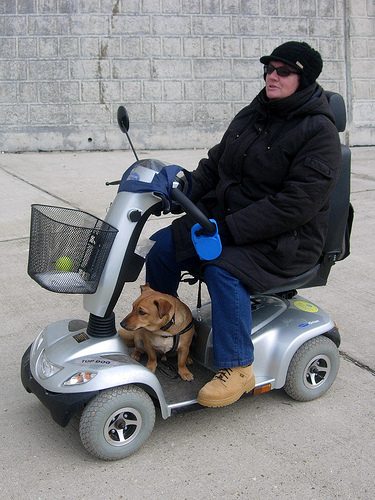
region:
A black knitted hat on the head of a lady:
[259, 40, 322, 86]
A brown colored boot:
[195, 366, 256, 405]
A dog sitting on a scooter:
[115, 286, 196, 380]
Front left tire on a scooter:
[76, 386, 155, 459]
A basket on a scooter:
[28, 200, 117, 294]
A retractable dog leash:
[190, 220, 222, 260]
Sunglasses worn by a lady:
[263, 63, 299, 76]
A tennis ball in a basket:
[54, 255, 72, 270]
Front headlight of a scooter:
[33, 348, 62, 376]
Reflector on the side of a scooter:
[252, 384, 270, 393]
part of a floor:
[289, 412, 310, 440]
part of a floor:
[248, 432, 285, 474]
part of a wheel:
[100, 428, 127, 454]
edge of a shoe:
[205, 393, 222, 408]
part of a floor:
[261, 437, 289, 468]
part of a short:
[203, 379, 221, 403]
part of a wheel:
[105, 420, 140, 452]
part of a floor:
[285, 424, 303, 453]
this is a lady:
[227, 32, 339, 294]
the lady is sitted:
[209, 37, 329, 293]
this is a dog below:
[124, 276, 199, 359]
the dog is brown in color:
[123, 283, 195, 359]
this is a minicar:
[26, 300, 112, 414]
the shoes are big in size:
[195, 369, 248, 401]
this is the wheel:
[91, 387, 147, 455]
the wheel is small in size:
[82, 386, 147, 456]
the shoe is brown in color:
[203, 372, 245, 400]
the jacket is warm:
[218, 117, 322, 223]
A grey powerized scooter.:
[18, 86, 363, 495]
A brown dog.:
[117, 288, 210, 382]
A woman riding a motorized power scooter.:
[17, 39, 353, 461]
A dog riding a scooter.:
[120, 273, 211, 401]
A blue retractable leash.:
[185, 217, 226, 323]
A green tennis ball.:
[56, 250, 72, 270]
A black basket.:
[27, 204, 118, 307]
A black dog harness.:
[152, 311, 194, 365]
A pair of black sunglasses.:
[260, 62, 302, 79]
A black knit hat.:
[252, 38, 325, 88]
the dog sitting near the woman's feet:
[118, 282, 195, 382]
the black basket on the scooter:
[26, 202, 118, 293]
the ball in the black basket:
[54, 256, 71, 270]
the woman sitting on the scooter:
[145, 40, 342, 407]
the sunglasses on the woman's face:
[262, 62, 302, 77]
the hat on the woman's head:
[260, 40, 322, 80]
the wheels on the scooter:
[79, 335, 340, 461]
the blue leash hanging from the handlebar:
[192, 218, 223, 324]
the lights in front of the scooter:
[33, 330, 98, 386]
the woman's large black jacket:
[178, 80, 341, 292]